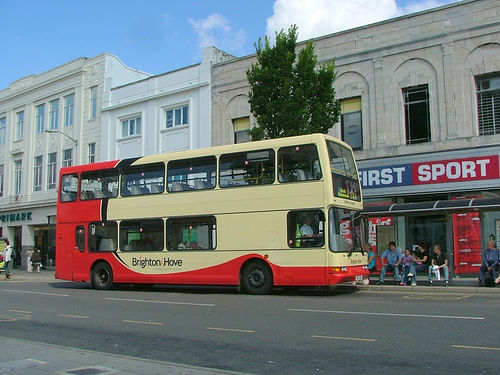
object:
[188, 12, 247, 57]
cloud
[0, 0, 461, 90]
sky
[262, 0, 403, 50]
cloud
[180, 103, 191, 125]
window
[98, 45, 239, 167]
building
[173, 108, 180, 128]
window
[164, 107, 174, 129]
window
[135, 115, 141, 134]
window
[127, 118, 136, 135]
window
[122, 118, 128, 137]
window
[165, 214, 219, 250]
window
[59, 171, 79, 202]
window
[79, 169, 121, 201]
window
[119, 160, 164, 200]
window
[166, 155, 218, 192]
window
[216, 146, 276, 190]
window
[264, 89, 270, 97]
leaf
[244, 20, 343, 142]
plant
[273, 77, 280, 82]
leaf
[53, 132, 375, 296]
bus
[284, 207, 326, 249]
window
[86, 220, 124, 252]
window